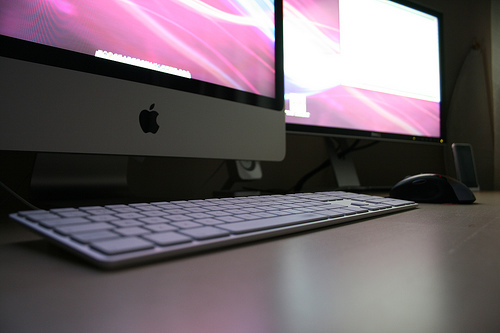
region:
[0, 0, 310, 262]
Computer is turn on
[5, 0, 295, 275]
Computer brand is apple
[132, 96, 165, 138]
Apple company logotype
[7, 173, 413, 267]
Keyboard of computer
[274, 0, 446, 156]
Screen of computer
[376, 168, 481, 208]
Mouse of computer is black and tan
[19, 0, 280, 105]
Screen of computer is purple and white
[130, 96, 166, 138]
Apple logotype is color black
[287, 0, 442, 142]
Screen of computer is white and black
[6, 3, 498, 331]
Computers are on a desk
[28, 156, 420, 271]
This is a keyboard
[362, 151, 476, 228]
This is a computer mouse.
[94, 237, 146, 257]
this is the ctrl button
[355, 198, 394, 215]
These are the arrow keys.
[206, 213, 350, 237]
This is the space bar.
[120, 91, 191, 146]
This is the apple logo.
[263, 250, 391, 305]
This is a wooden desk.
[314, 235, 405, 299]
This is reflecting purple.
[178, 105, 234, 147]
This is a white monitor.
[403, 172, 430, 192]
This is the color black.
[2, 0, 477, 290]
The computer sits on a table.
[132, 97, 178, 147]
The computer has the Apple logo.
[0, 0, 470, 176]
The computer has two monitors.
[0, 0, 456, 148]
The monitors' screens are pink.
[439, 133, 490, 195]
The computer has speakers.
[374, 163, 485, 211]
The computer has a mouse.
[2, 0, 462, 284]
The computers are silver and black.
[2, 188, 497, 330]
The tabletop is grey.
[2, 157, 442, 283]
The keyboard is flat.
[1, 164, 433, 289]
The keyboard is white.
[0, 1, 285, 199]
imac, probably brushed silvertone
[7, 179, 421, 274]
flat mac keyboard, raised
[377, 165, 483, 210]
non-native mac mouse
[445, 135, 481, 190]
little speaker or charing cellphone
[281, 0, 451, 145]
monitor, looks like pc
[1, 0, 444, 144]
identical appearing blown-out pink backgrounds on two monitors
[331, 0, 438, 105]
window on monitor that looks empty, but is blown out so who knows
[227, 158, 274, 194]
tiny speaker, i think, hooked to mac, i think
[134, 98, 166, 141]
apple logo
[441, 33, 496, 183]
ironing board in darkened background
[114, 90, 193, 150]
Apple logo on monitor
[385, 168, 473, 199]
Black computer mouse on desk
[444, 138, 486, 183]
speaker for listening on desk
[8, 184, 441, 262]
Keyboard in front of monitor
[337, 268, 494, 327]
One large brown desk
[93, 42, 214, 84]
Words on the monitor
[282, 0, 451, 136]
Second monitor on desk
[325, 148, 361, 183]
Monitor stand below monitor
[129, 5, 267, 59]
Pink hue on screen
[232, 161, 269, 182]
speaker hanging from monitor